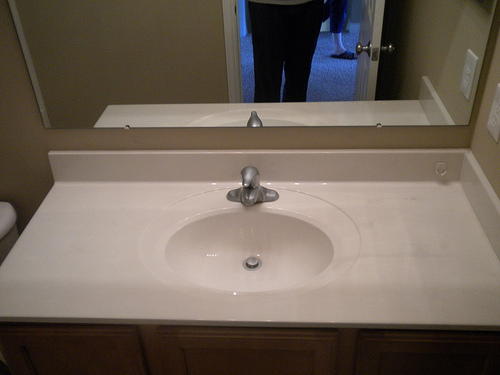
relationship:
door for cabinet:
[355, 331, 497, 373] [2, 320, 498, 373]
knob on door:
[378, 32, 397, 58] [341, 0, 398, 102]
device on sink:
[434, 161, 446, 176] [6, 149, 496, 324]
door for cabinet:
[161, 329, 350, 374] [0, 142, 499, 371]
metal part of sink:
[226, 165, 274, 206] [6, 149, 496, 324]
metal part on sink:
[226, 165, 274, 206] [166, 206, 326, 289]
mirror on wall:
[8, 1, 499, 130] [1, 6, 484, 148]